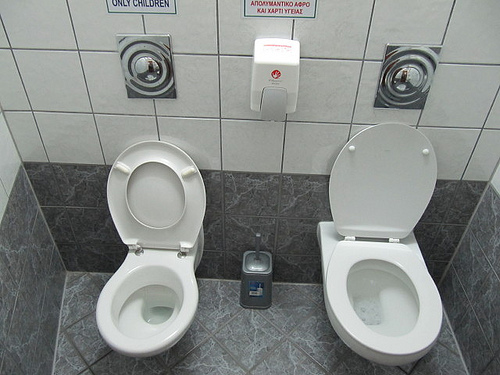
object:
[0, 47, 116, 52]
grout line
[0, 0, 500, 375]
wall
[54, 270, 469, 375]
ground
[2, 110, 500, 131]
line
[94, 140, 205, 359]
toilet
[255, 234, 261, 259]
brush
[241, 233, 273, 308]
holder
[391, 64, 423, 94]
button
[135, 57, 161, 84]
button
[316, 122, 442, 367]
toilet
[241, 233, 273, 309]
cleaner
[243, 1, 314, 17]
white sign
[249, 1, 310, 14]
red lettering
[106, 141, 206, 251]
lid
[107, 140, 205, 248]
seat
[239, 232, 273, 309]
toilet brush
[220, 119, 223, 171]
grout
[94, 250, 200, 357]
toilet bowl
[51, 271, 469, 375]
floor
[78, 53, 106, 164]
grout line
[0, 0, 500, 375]
bathroom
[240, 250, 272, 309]
bowl cleaner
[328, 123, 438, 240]
lid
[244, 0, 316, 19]
sign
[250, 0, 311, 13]
lettering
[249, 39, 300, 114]
dispenser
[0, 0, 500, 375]
tile